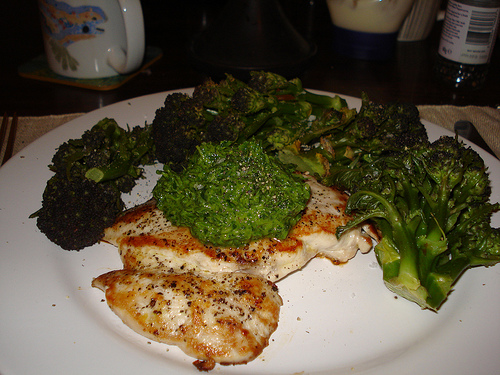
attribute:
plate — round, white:
[1, 87, 498, 373]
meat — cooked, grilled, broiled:
[92, 172, 379, 371]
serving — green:
[152, 141, 310, 245]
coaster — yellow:
[17, 41, 162, 91]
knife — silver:
[453, 121, 497, 160]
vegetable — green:
[37, 66, 498, 307]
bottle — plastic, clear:
[325, 1, 415, 61]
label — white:
[439, 2, 499, 65]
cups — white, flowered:
[39, 3, 145, 81]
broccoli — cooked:
[147, 73, 354, 167]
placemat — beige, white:
[2, 101, 494, 175]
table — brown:
[3, 3, 499, 116]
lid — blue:
[330, 24, 399, 66]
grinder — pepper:
[434, 0, 496, 102]